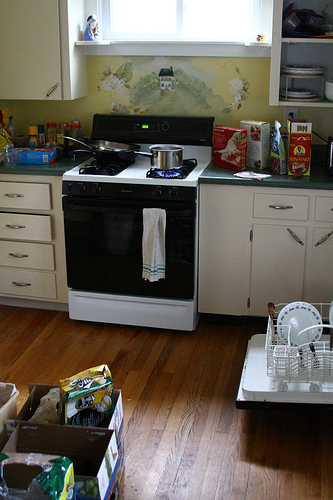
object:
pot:
[125, 144, 185, 171]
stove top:
[61, 161, 210, 182]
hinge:
[247, 297, 251, 308]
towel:
[141, 206, 167, 283]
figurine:
[83, 14, 100, 41]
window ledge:
[73, 37, 272, 48]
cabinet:
[277, 40, 333, 106]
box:
[285, 119, 313, 177]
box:
[239, 118, 271, 170]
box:
[213, 125, 247, 171]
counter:
[198, 145, 333, 187]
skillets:
[57, 134, 142, 166]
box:
[58, 362, 114, 425]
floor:
[1, 304, 329, 499]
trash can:
[0, 380, 20, 437]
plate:
[276, 300, 323, 348]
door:
[249, 225, 310, 317]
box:
[15, 382, 126, 483]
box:
[0, 450, 76, 499]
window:
[101, 0, 258, 42]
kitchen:
[0, 0, 332, 499]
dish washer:
[235, 299, 333, 411]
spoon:
[266, 301, 276, 344]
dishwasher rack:
[263, 302, 332, 385]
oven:
[60, 112, 215, 334]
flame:
[156, 170, 182, 177]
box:
[0, 423, 121, 499]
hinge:
[249, 230, 253, 242]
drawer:
[0, 181, 51, 211]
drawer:
[0, 212, 53, 243]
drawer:
[0, 240, 58, 273]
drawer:
[0, 267, 57, 300]